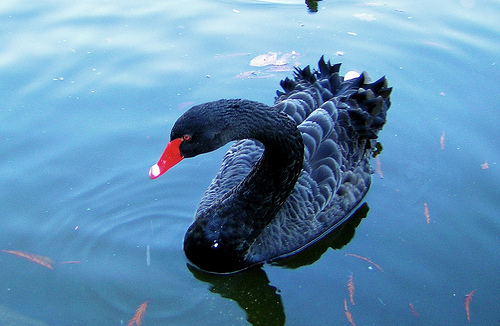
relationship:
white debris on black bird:
[211, 239, 221, 251] [146, 54, 395, 275]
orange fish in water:
[122, 298, 152, 324] [1, 1, 499, 325]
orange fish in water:
[340, 267, 361, 302] [1, 1, 499, 325]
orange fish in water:
[420, 201, 431, 224] [1, 1, 499, 325]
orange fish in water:
[413, 195, 431, 228] [1, 1, 499, 325]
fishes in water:
[438, 130, 446, 150] [1, 1, 499, 325]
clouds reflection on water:
[28, 19, 200, 88] [1, 1, 499, 325]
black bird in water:
[150, 54, 397, 279] [1, 1, 499, 325]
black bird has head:
[146, 54, 395, 275] [122, 98, 319, 198]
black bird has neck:
[146, 54, 395, 275] [216, 83, 323, 314]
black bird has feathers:
[146, 54, 395, 275] [266, 70, 411, 210]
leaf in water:
[235, 49, 303, 79] [1, 1, 499, 325]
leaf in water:
[235, 49, 303, 79] [37, 32, 160, 136]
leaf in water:
[214, 24, 335, 96] [1, 1, 499, 325]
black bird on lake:
[146, 54, 395, 275] [44, 22, 119, 148]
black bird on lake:
[146, 54, 395, 275] [1, 1, 500, 323]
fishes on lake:
[424, 124, 484, 184] [1, 1, 500, 323]